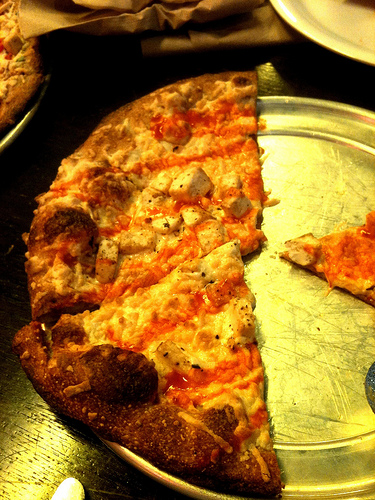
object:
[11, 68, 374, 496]
pizza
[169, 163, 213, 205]
chicken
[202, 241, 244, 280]
chicken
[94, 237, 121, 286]
chicken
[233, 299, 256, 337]
chicken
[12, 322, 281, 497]
crust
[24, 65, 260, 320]
crust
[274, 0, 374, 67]
pizza pan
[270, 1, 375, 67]
edge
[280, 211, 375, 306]
slice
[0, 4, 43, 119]
pizza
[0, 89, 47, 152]
edge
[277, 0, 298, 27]
reflection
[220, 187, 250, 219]
chicken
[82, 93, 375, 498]
pizza tray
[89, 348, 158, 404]
air bubble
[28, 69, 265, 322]
cheese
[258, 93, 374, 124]
edge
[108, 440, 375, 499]
edge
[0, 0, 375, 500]
table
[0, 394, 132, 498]
wear and tear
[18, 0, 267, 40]
napkin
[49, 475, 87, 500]
knife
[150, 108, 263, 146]
sauce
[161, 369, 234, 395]
sauce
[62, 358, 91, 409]
cheese